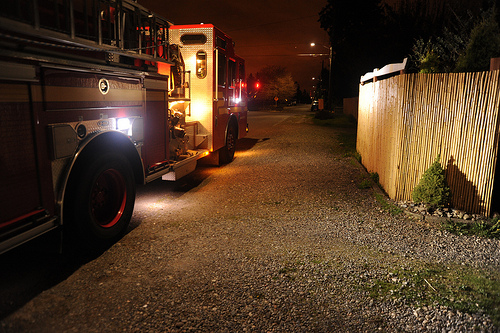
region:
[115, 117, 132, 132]
the light on the truck is on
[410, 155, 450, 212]
a small green tree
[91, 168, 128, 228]
the tire rim is red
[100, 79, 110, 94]
silver gas cap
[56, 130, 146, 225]
the fender is metal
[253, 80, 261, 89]
the street signal is red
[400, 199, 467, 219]
rocks under the tree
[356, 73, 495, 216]
wooden fence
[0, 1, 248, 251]
a red fire truck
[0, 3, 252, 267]
the truck is parked on the street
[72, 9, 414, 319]
a fire truck on the road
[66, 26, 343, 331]
a fire truck on the street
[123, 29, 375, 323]
a road with a fire truck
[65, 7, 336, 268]
a street with a fire truck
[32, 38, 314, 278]
a red fire truck on the road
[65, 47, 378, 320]
a red fire truck on a street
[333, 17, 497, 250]
a tall fence outside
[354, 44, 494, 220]
a brown fence outside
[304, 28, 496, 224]
a tall brown fence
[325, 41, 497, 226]
a tall brown fence outside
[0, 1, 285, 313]
truck on the road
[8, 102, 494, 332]
gravel on the side of the road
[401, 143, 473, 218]
small green plant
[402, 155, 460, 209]
plant in front of the fence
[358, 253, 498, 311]
green grass on the gravel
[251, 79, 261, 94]
traffic light shining red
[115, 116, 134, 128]
light on the side of the trick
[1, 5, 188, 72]
ladder on the side of the truck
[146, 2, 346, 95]
the sky is dark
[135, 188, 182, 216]
light shining on the ground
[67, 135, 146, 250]
black tire and red rim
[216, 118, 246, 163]
black tire of a fire truck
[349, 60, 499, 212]
fence made of wooden boards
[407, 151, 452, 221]
small tree with green leaves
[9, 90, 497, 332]
sidewalk is covered in gravel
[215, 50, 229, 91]
window on a fire truck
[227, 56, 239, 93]
window on a fire truck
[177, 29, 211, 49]
window on a fire truck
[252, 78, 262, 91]
light on a fire truck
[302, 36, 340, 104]
street light on a metal pole